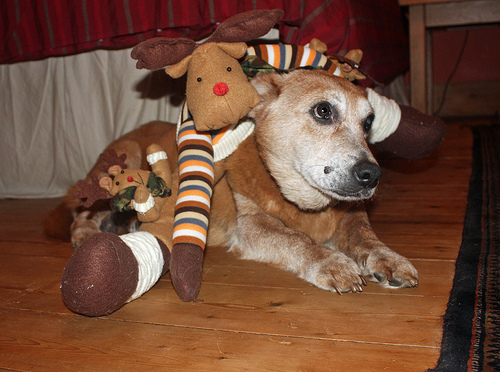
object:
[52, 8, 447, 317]
toys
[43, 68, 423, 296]
dog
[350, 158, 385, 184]
nose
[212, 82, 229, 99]
nose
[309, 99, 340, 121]
eye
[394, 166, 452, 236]
floor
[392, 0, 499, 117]
table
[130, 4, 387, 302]
reindeer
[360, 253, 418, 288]
paw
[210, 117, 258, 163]
skirt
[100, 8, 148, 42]
mistletoe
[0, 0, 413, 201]
bed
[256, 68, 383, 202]
face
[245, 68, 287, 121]
ear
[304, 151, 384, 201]
mouth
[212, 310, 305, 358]
fur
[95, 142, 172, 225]
moose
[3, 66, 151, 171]
cloth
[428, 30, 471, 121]
cord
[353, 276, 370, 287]
nail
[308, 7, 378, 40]
material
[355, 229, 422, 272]
feet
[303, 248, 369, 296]
claw